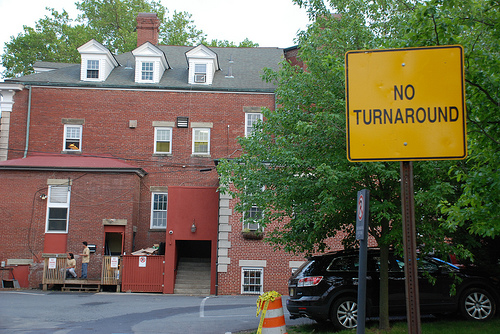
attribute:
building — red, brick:
[3, 10, 413, 317]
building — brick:
[22, 40, 418, 302]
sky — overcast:
[0, 1, 324, 45]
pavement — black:
[0, 292, 307, 332]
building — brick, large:
[9, 18, 300, 308]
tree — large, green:
[274, 76, 474, 220]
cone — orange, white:
[254, 288, 290, 331]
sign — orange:
[348, 49, 462, 159]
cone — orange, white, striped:
[255, 290, 291, 332]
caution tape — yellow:
[256, 285, 278, 332]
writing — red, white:
[354, 224, 364, 238]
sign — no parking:
[352, 183, 372, 244]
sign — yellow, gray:
[341, 43, 463, 168]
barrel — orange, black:
[248, 280, 296, 332]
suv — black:
[249, 209, 451, 331]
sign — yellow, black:
[326, 52, 466, 172]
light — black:
[173, 116, 186, 133]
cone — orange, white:
[248, 293, 286, 331]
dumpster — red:
[120, 255, 164, 296]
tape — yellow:
[256, 291, 277, 329]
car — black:
[287, 245, 497, 329]